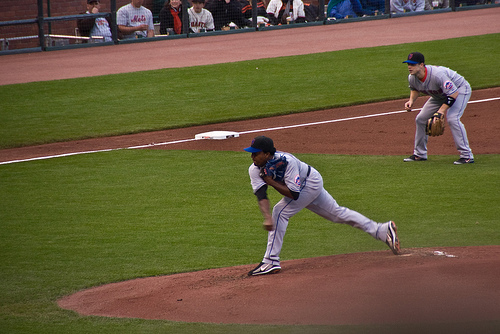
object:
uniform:
[249, 150, 389, 264]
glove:
[257, 162, 287, 180]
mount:
[57, 246, 499, 325]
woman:
[157, 2, 194, 37]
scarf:
[163, 7, 184, 39]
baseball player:
[400, 50, 475, 163]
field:
[0, 10, 499, 333]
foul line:
[0, 97, 499, 166]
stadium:
[0, 0, 499, 332]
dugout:
[0, 0, 499, 50]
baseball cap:
[402, 50, 427, 67]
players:
[67, 0, 497, 42]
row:
[0, 0, 499, 52]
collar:
[410, 69, 430, 85]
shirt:
[407, 63, 474, 110]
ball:
[0, 0, 499, 333]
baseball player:
[246, 134, 398, 276]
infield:
[0, 8, 499, 333]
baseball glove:
[423, 115, 446, 138]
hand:
[424, 114, 447, 137]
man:
[111, 2, 158, 42]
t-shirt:
[118, 6, 155, 34]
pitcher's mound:
[53, 245, 499, 326]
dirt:
[59, 244, 499, 324]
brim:
[239, 147, 260, 155]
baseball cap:
[244, 137, 275, 152]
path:
[2, 88, 484, 170]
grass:
[2, 31, 499, 333]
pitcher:
[240, 135, 403, 276]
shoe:
[382, 221, 399, 254]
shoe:
[248, 257, 284, 276]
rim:
[241, 146, 261, 156]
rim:
[399, 58, 419, 65]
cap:
[403, 51, 426, 65]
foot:
[451, 155, 478, 167]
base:
[192, 131, 242, 140]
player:
[400, 46, 477, 167]